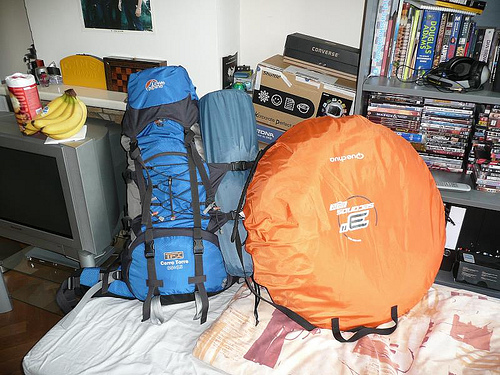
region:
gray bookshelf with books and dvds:
[353, 0, 499, 298]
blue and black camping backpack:
[76, 63, 236, 324]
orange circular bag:
[245, 111, 448, 327]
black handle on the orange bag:
[330, 303, 402, 344]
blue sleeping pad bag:
[198, 88, 270, 279]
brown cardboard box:
[248, 52, 361, 129]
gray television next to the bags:
[2, 118, 122, 255]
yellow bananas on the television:
[19, 86, 90, 140]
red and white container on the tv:
[2, 70, 42, 124]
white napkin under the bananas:
[43, 122, 89, 145]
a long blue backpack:
[77, 62, 231, 304]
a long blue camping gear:
[196, 89, 260, 280]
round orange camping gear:
[240, 115, 448, 331]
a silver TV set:
[3, 111, 128, 267]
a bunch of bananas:
[22, 88, 87, 138]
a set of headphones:
[397, 51, 487, 93]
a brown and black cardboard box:
[252, 53, 354, 134]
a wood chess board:
[102, 56, 164, 96]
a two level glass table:
[0, 240, 94, 316]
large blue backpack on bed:
[95, 45, 253, 323]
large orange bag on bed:
[235, 123, 463, 334]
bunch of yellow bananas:
[27, 79, 82, 150]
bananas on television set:
[26, 92, 110, 154]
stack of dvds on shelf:
[465, 103, 499, 177]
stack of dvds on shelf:
[422, 98, 473, 182]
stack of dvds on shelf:
[372, 93, 420, 141]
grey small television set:
[0, 98, 160, 288]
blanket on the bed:
[195, 273, 373, 370]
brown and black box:
[283, 15, 361, 83]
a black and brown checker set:
[104, 56, 168, 96]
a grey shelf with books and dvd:
[350, 0, 497, 298]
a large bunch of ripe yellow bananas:
[19, 88, 87, 140]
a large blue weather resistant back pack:
[57, 63, 259, 322]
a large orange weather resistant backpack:
[229, 113, 447, 342]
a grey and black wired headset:
[395, 51, 490, 93]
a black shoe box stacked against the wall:
[280, 30, 360, 82]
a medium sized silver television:
[0, 112, 129, 270]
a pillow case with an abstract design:
[193, 280, 498, 373]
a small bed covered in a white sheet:
[22, 272, 497, 374]